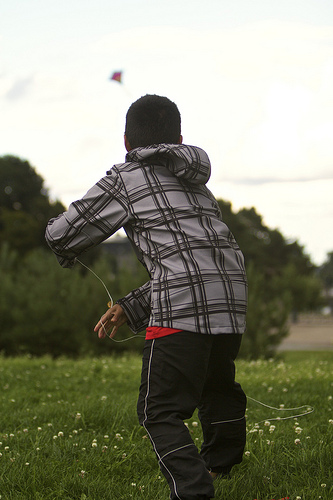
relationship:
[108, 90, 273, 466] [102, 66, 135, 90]
boy flying kite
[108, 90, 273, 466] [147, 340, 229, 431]
boy wearing pants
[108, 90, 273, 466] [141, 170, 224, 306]
boy wearing jacket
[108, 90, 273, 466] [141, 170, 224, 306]
boy in jacket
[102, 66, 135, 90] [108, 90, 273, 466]
kite above boy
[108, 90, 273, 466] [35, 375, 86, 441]
boy on grass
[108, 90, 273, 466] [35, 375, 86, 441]
boy above grass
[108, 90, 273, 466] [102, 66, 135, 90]
boy holding kite